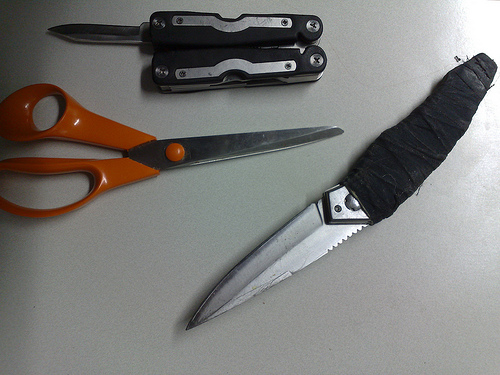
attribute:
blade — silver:
[179, 198, 326, 346]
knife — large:
[189, 46, 480, 346]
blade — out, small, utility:
[48, 17, 154, 55]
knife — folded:
[38, 12, 321, 40]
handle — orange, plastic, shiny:
[4, 83, 157, 225]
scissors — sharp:
[4, 83, 348, 219]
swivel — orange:
[160, 142, 186, 171]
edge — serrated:
[261, 235, 350, 303]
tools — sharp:
[114, 8, 380, 298]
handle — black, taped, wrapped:
[372, 51, 479, 217]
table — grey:
[337, 15, 384, 95]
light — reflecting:
[462, 5, 494, 142]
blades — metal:
[196, 124, 345, 159]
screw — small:
[280, 16, 288, 29]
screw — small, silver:
[274, 54, 295, 75]